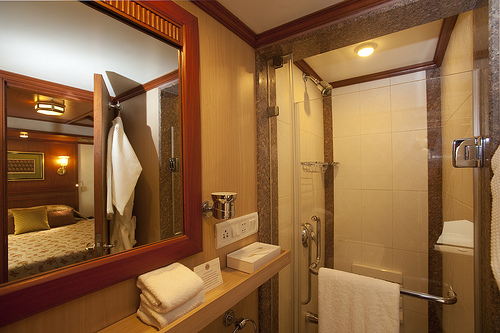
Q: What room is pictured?
A: It is a bathroom.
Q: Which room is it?
A: It is a bathroom.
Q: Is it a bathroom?
A: Yes, it is a bathroom.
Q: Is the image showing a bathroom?
A: Yes, it is showing a bathroom.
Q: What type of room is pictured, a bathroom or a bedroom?
A: It is a bathroom.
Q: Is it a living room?
A: No, it is a bathroom.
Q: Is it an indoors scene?
A: Yes, it is indoors.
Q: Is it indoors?
A: Yes, it is indoors.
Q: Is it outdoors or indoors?
A: It is indoors.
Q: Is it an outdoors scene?
A: No, it is indoors.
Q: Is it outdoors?
A: No, it is indoors.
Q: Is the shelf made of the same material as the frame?
A: Yes, both the shelf and the frame are made of wood.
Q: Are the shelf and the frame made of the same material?
A: Yes, both the shelf and the frame are made of wood.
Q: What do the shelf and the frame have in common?
A: The material, both the shelf and the frame are wooden.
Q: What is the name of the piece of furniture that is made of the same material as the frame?
A: The piece of furniture is a shelf.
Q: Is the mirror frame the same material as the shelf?
A: Yes, both the frame and the shelf are made of wood.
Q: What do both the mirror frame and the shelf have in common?
A: The material, both the frame and the shelf are wooden.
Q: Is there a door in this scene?
A: Yes, there is a door.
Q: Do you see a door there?
A: Yes, there is a door.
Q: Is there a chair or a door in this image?
A: Yes, there is a door.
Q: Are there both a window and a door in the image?
A: No, there is a door but no windows.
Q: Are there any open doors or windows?
A: Yes, there is an open door.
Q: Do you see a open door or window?
A: Yes, there is an open door.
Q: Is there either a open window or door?
A: Yes, there is an open door.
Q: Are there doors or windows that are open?
A: Yes, the door is open.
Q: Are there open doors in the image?
A: Yes, there is an open door.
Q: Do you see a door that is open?
A: Yes, there is a door that is open.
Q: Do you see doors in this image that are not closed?
A: Yes, there is a open door.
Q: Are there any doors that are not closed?
A: Yes, there is a open door.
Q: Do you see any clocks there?
A: No, there are no clocks.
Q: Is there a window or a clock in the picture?
A: No, there are no clocks or windows.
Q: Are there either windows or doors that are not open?
A: No, there is a door but it is open.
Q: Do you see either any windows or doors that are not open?
A: No, there is a door but it is open.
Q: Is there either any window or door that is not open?
A: No, there is a door but it is open.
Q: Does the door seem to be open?
A: Yes, the door is open.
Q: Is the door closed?
A: No, the door is open.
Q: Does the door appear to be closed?
A: No, the door is open.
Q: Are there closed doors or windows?
A: No, there is a door but it is open.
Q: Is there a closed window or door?
A: No, there is a door but it is open.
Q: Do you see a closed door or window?
A: No, there is a door but it is open.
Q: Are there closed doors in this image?
A: No, there is a door but it is open.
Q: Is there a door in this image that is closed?
A: No, there is a door but it is open.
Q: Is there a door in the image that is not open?
A: No, there is a door but it is open.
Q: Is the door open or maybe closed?
A: The door is open.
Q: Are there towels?
A: Yes, there is a towel.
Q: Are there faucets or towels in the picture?
A: Yes, there is a towel.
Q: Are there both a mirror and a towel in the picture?
A: Yes, there are both a towel and a mirror.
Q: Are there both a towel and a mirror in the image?
A: Yes, there are both a towel and a mirror.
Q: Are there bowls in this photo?
A: No, there are no bowls.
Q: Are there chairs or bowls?
A: No, there are no bowls or chairs.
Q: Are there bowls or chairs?
A: No, there are no bowls or chairs.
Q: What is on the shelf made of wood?
A: The towel is on the shelf.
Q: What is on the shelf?
A: The towel is on the shelf.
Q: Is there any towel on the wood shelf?
A: Yes, there is a towel on the shelf.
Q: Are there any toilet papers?
A: No, there are no toilet papers.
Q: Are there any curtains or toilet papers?
A: No, there are no toilet papers or curtains.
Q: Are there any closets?
A: No, there are no closets.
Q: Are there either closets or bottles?
A: No, there are no closets or bottles.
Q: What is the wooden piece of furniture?
A: The piece of furniture is a shelf.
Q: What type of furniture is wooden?
A: The furniture is a shelf.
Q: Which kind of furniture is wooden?
A: The furniture is a shelf.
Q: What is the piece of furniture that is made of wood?
A: The piece of furniture is a shelf.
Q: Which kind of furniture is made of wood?
A: The furniture is a shelf.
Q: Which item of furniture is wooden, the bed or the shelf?
A: The shelf is wooden.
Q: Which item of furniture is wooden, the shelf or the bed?
A: The shelf is wooden.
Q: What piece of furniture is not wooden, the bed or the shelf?
A: The bed is not wooden.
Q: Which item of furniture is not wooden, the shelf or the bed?
A: The bed is not wooden.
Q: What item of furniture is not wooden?
A: The piece of furniture is a bed.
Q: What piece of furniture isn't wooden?
A: The piece of furniture is a bed.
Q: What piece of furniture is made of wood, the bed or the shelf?
A: The shelf is made of wood.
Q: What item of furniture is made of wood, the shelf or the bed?
A: The shelf is made of wood.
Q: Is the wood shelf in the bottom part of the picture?
A: Yes, the shelf is in the bottom of the image.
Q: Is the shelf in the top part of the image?
A: No, the shelf is in the bottom of the image.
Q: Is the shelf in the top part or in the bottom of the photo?
A: The shelf is in the bottom of the image.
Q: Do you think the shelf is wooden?
A: Yes, the shelf is wooden.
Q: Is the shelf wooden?
A: Yes, the shelf is wooden.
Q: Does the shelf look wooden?
A: Yes, the shelf is wooden.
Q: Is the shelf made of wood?
A: Yes, the shelf is made of wood.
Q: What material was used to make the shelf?
A: The shelf is made of wood.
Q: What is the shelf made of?
A: The shelf is made of wood.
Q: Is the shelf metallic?
A: No, the shelf is wooden.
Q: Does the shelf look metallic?
A: No, the shelf is wooden.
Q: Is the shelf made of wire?
A: No, the shelf is made of wood.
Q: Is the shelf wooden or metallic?
A: The shelf is wooden.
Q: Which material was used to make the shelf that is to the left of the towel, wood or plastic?
A: The shelf is made of wood.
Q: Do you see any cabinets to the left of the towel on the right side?
A: No, there is a shelf to the left of the towel.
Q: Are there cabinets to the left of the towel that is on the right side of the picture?
A: No, there is a shelf to the left of the towel.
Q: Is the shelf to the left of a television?
A: No, the shelf is to the left of the towel.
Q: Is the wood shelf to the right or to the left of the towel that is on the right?
A: The shelf is to the left of the towel.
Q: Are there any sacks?
A: No, there are no sacks.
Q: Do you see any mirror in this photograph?
A: Yes, there is a mirror.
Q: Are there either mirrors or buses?
A: Yes, there is a mirror.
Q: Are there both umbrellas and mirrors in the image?
A: No, there is a mirror but no umbrellas.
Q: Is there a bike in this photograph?
A: No, there are no bikes.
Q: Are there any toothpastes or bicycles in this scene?
A: No, there are no bicycles or toothpastes.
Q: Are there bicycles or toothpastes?
A: No, there are no bicycles or toothpastes.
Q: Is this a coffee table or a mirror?
A: This is a mirror.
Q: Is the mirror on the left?
A: Yes, the mirror is on the left of the image.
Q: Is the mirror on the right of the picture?
A: No, the mirror is on the left of the image.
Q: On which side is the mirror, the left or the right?
A: The mirror is on the left of the image.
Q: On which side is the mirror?
A: The mirror is on the left of the image.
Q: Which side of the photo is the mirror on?
A: The mirror is on the left of the image.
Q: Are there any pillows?
A: Yes, there are pillows.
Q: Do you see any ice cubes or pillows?
A: Yes, there are pillows.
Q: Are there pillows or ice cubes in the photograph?
A: Yes, there are pillows.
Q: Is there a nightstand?
A: No, there are no nightstands.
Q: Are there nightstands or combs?
A: No, there are no nightstands or combs.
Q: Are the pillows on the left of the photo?
A: Yes, the pillows are on the left of the image.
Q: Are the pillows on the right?
A: No, the pillows are on the left of the image.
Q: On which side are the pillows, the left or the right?
A: The pillows are on the left of the image.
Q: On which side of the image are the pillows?
A: The pillows are on the left of the image.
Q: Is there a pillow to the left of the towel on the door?
A: Yes, there are pillows to the left of the towel.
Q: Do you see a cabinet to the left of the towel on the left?
A: No, there are pillows to the left of the towel.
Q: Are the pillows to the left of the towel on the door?
A: Yes, the pillows are to the left of the towel.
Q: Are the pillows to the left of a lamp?
A: No, the pillows are to the left of the towel.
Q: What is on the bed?
A: The pillows are on the bed.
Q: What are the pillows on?
A: The pillows are on the bed.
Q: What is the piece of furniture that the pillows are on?
A: The piece of furniture is a bed.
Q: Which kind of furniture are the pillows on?
A: The pillows are on the bed.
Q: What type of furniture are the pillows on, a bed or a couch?
A: The pillows are on a bed.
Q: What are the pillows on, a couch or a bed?
A: The pillows are on a bed.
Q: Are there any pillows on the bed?
A: Yes, there are pillows on the bed.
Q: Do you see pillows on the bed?
A: Yes, there are pillows on the bed.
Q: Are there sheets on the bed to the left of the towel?
A: No, there are pillows on the bed.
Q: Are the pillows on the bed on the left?
A: Yes, the pillows are on the bed.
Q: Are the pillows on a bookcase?
A: No, the pillows are on the bed.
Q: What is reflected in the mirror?
A: The pillows are reflected in the mirror.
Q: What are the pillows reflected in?
A: The pillows are reflected in the mirror.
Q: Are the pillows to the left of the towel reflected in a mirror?
A: Yes, the pillows are reflected in a mirror.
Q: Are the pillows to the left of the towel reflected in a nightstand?
A: No, the pillows are reflected in a mirror.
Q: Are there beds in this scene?
A: Yes, there is a bed.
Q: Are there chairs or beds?
A: Yes, there is a bed.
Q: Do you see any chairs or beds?
A: Yes, there is a bed.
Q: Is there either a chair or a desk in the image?
A: No, there are no chairs or desks.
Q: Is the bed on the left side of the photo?
A: Yes, the bed is on the left of the image.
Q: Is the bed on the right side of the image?
A: No, the bed is on the left of the image.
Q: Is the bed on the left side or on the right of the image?
A: The bed is on the left of the image.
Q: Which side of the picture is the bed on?
A: The bed is on the left of the image.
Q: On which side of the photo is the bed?
A: The bed is on the left of the image.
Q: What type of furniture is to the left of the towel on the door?
A: The piece of furniture is a bed.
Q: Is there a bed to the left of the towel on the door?
A: Yes, there is a bed to the left of the towel.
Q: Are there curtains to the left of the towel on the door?
A: No, there is a bed to the left of the towel.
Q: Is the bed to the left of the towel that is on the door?
A: Yes, the bed is to the left of the towel.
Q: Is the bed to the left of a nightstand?
A: No, the bed is to the left of the towel.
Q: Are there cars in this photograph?
A: No, there are no cars.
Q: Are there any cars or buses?
A: No, there are no cars or buses.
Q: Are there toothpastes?
A: No, there are no toothpastes.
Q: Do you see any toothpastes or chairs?
A: No, there are no toothpastes or chairs.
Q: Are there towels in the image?
A: Yes, there is a towel.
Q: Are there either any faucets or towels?
A: Yes, there is a towel.